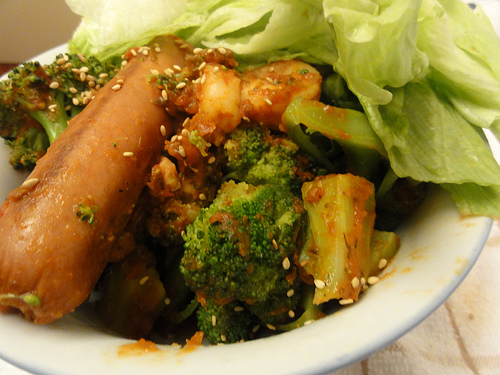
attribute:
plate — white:
[400, 244, 461, 317]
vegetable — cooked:
[17, 30, 423, 310]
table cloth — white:
[324, 221, 498, 374]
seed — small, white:
[313, 277, 325, 290]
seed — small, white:
[337, 299, 353, 305]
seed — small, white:
[351, 278, 358, 290]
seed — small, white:
[367, 276, 377, 286]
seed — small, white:
[379, 260, 386, 269]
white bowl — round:
[0, 38, 500, 373]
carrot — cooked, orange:
[1, 32, 197, 325]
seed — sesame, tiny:
[120, 148, 135, 160]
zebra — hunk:
[187, 137, 307, 342]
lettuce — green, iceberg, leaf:
[52, 0, 499, 221]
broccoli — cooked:
[165, 131, 313, 346]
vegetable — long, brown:
[3, 5, 498, 321]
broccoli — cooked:
[184, 182, 311, 334]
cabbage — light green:
[66, 1, 498, 214]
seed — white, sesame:
[311, 275, 327, 292]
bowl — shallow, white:
[0, 1, 495, 371]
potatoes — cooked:
[167, 58, 319, 151]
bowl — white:
[1, 38, 493, 373]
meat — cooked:
[2, 30, 192, 329]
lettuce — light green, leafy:
[98, 6, 493, 223]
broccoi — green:
[0, 49, 400, 348]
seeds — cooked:
[20, 38, 387, 373]